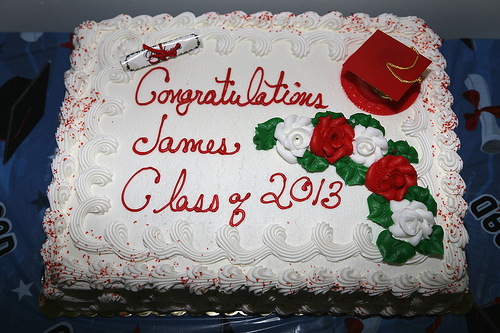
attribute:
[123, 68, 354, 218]
writing — red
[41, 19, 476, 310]
cake — white, frosted, sprinkled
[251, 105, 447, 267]
flowers — green, white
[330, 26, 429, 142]
hat — red, gold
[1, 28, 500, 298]
cloth — blue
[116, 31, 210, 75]
diploma — white